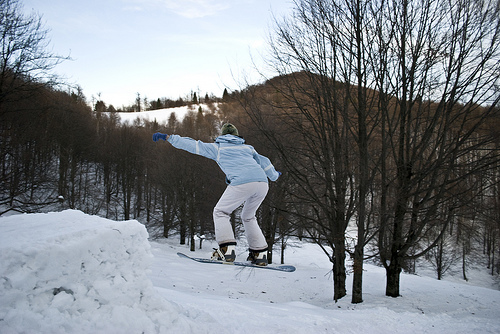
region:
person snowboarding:
[133, 106, 316, 284]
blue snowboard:
[179, 246, 296, 276]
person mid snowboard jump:
[146, 111, 310, 298]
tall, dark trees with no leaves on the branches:
[275, 3, 499, 295]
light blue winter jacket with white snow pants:
[164, 126, 301, 258]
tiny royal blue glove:
[146, 123, 167, 145]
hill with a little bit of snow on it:
[126, 66, 498, 158]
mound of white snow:
[1, 208, 170, 332]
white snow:
[168, 262, 497, 331]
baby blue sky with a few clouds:
[24, 1, 498, 98]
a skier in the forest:
[8, 5, 494, 325]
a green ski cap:
[214, 115, 242, 142]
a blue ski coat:
[154, 130, 296, 191]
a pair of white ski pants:
[211, 177, 284, 264]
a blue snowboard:
[169, 242, 304, 284]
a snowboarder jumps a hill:
[135, 102, 329, 292]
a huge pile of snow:
[0, 187, 187, 332]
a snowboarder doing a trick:
[9, 7, 494, 324]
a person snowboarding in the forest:
[6, 2, 494, 326]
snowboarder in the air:
[140, 106, 315, 290]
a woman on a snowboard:
[151, 121, 296, 272]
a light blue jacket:
[168, 130, 279, 182]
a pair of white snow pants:
[211, 177, 270, 248]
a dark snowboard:
[177, 250, 294, 271]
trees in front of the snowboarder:
[0, 0, 499, 306]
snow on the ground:
[0, 160, 499, 332]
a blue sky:
[0, 0, 499, 110]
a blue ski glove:
[153, 130, 165, 140]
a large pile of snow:
[0, 207, 155, 332]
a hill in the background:
[101, 69, 499, 138]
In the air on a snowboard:
[143, 110, 335, 290]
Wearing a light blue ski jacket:
[126, 96, 294, 196]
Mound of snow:
[4, 179, 196, 331]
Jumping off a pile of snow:
[1, 84, 325, 324]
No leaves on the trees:
[236, 3, 497, 309]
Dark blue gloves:
[140, 118, 182, 153]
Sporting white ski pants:
[196, 170, 296, 254]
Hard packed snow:
[24, 197, 292, 328]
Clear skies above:
[28, 7, 300, 111]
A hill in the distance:
[206, 66, 480, 130]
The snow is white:
[6, 222, 188, 287]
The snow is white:
[24, 202, 157, 315]